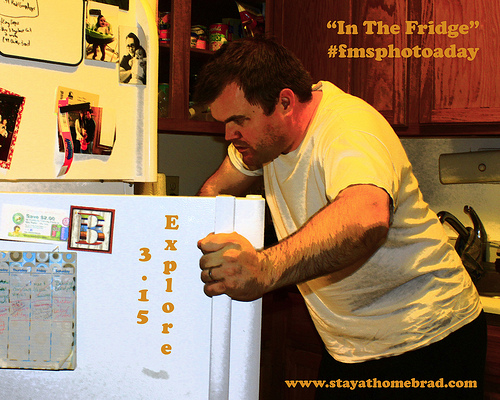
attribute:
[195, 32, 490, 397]
man — staring, leaning down, looking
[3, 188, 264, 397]
door — open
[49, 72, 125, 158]
photos — hanging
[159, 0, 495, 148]
cabinets — brown, wooden, wood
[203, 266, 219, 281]
ring — wedding ring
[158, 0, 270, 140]
cabinet — wooden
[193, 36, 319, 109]
hair — short, brown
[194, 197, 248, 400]
handle — long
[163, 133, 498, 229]
wall — white